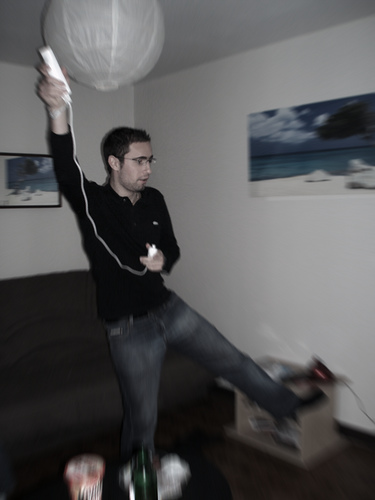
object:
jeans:
[87, 289, 316, 486]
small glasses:
[109, 147, 164, 169]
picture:
[1, 151, 65, 209]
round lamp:
[39, 0, 170, 89]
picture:
[243, 91, 374, 200]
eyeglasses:
[115, 155, 157, 165]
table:
[245, 349, 306, 441]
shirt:
[43, 123, 180, 321]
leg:
[165, 292, 328, 422]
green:
[142, 473, 152, 485]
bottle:
[132, 440, 154, 496]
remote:
[33, 42, 75, 108]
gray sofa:
[12, 273, 215, 457]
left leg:
[175, 301, 340, 436]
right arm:
[33, 55, 96, 204]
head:
[87, 109, 175, 203]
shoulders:
[61, 178, 177, 221]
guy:
[36, 62, 318, 461]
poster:
[245, 89, 374, 197]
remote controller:
[40, 46, 158, 275]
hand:
[37, 63, 65, 115]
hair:
[98, 125, 150, 169]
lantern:
[36, 3, 172, 97]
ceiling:
[2, 0, 373, 86]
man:
[34, 63, 329, 493]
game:
[40, 43, 160, 275]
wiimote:
[37, 44, 72, 95]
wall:
[126, 14, 373, 429]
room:
[2, 1, 373, 496]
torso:
[59, 104, 245, 402]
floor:
[7, 285, 352, 499]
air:
[196, 289, 333, 439]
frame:
[0, 153, 61, 207]